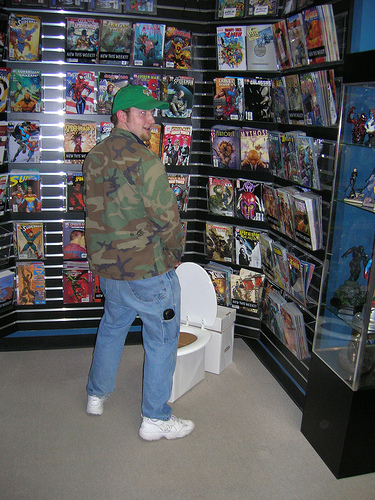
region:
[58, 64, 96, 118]
Comic book hanging on the wall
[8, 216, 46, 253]
Comic book hanging on the wall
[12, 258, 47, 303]
Comic book hanging on the wall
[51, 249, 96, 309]
Comic book hanging on the wall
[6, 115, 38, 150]
Comic book hanging on the wall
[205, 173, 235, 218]
Comic book hanging on the wall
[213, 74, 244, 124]
Comic book hanging on the wall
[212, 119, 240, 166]
Comic book hanging on the wall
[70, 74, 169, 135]
Green hat on a head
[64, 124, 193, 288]
Camo jacket on a man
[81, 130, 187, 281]
Green and tan camo jacket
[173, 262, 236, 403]
White toilet in middle of floor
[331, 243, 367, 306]
Figurine inside glass case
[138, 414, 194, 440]
White shoe on man's foot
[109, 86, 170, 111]
Green cap on man's head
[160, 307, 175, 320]
Black case inside man's pocket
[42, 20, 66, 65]
Light shining off of metal shelf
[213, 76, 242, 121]
Comic book sitting on shelf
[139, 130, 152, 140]
Beard on man's face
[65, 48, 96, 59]
Sign on front of bookshelf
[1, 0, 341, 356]
several racks of comic books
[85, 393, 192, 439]
a pair of white tennis shoes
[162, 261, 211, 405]
a small white toilet in corner of rack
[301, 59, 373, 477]
a stand up showcase of figurines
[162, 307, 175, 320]
black phone in small pocket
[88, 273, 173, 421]
a pair of blue denim jeans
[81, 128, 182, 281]
a camouflage jacket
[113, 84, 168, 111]
a clean green ball cap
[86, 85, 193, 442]
guy pretending to use toilet prop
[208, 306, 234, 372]
a white cardboard box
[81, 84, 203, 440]
a man standing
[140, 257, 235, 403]
a toilet on the floor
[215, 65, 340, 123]
comic books on the wall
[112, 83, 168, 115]
a green hat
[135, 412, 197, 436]
white tennis shoes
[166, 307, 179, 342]
a cell phone in pocket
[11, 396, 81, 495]
a gray concrete floor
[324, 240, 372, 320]
statues in glass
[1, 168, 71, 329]
a black and white wall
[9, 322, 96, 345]
a blue line on the wall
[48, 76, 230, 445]
man in a camo coat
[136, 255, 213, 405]
fake toilet near display shelving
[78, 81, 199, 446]
man pretending to urinate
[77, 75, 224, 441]
man in a green hat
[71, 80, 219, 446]
man wearing white sneakers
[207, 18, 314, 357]
shelves featuring comic books or magazines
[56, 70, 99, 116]
marvel's superhero Spider Man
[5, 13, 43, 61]
DC's superhero comic for Superman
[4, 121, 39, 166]
A joint comic featuring superman and batman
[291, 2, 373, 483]
clear display case with a black base